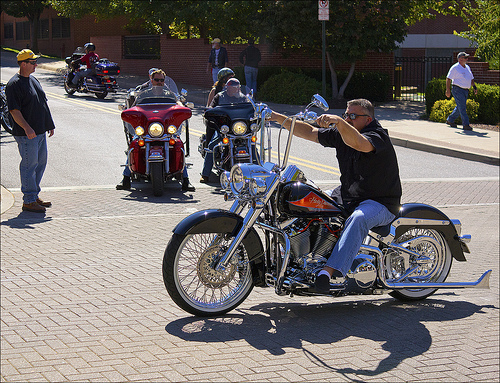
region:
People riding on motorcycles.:
[111, 54, 495, 331]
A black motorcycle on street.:
[140, 158, 488, 315]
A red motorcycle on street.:
[113, 87, 198, 187]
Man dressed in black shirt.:
[311, 113, 406, 218]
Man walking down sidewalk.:
[441, 44, 493, 137]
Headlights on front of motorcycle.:
[133, 118, 188, 140]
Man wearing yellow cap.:
[9, 44, 44, 64]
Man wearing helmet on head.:
[79, 42, 99, 53]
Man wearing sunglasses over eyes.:
[148, 72, 172, 84]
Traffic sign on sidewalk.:
[306, 0, 340, 105]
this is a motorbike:
[169, 128, 473, 335]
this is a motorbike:
[99, 88, 206, 193]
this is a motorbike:
[186, 102, 273, 189]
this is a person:
[126, 50, 183, 132]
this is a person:
[0, 39, 65, 225]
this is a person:
[201, 65, 258, 141]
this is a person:
[438, 42, 487, 140]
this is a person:
[72, 35, 102, 73]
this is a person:
[209, 59, 258, 111]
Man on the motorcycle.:
[154, 86, 497, 331]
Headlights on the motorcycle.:
[127, 118, 184, 140]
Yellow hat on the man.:
[12, 45, 44, 82]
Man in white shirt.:
[442, 46, 479, 94]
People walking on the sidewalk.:
[205, 30, 263, 100]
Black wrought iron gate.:
[396, 52, 453, 99]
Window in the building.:
[114, 12, 165, 65]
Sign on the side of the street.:
[312, 0, 332, 100]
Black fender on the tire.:
[162, 201, 272, 302]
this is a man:
[300, 72, 420, 343]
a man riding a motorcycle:
[142, 73, 472, 313]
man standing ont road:
[0, 45, 68, 242]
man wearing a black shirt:
[297, 113, 425, 218]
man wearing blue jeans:
[294, 151, 396, 266]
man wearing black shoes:
[297, 267, 340, 303]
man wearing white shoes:
[316, 261, 333, 273]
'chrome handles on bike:
[213, 78, 319, 225]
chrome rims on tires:
[143, 205, 265, 318]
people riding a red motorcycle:
[116, 58, 211, 195]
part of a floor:
[86, 305, 113, 335]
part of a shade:
[358, 313, 370, 325]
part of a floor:
[250, 343, 279, 381]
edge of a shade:
[289, 331, 311, 344]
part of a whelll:
[203, 304, 234, 336]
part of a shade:
[366, 332, 391, 367]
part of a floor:
[130, 338, 159, 361]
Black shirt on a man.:
[317, 121, 402, 217]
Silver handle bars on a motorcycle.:
[241, 100, 323, 170]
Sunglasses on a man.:
[339, 105, 373, 123]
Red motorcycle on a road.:
[105, 82, 194, 197]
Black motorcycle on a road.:
[205, 83, 269, 184]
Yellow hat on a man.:
[12, 45, 44, 63]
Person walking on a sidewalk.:
[238, 34, 265, 101]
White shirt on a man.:
[445, 57, 477, 91]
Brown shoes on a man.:
[22, 197, 51, 214]